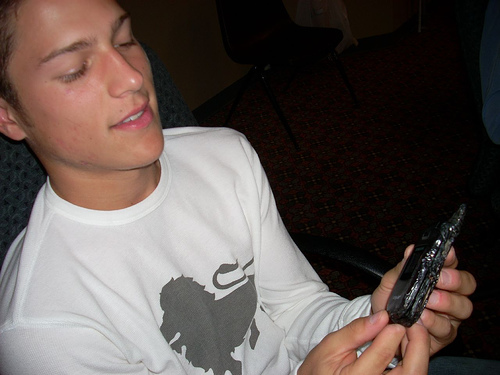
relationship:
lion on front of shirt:
[159, 257, 266, 374] [0, 125, 398, 373]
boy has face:
[1, 2, 266, 373] [35, 10, 163, 153]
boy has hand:
[1, 2, 266, 373] [381, 244, 467, 348]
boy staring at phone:
[1, 2, 266, 373] [387, 207, 464, 325]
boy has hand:
[1, 2, 266, 373] [298, 308, 431, 375]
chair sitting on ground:
[214, 0, 362, 148] [199, 0, 499, 362]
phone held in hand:
[387, 207, 464, 325] [381, 244, 467, 348]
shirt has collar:
[0, 125, 398, 373] [44, 151, 170, 225]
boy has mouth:
[1, 2, 266, 373] [108, 97, 154, 131]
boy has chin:
[1, 2, 266, 373] [130, 127, 165, 168]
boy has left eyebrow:
[1, 2, 266, 373] [110, 10, 133, 41]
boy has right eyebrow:
[1, 2, 266, 373] [35, 35, 93, 68]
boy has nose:
[1, 2, 266, 373] [105, 45, 145, 99]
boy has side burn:
[1, 2, 266, 373] [1, 84, 36, 129]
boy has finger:
[1, 2, 266, 373] [339, 323, 406, 374]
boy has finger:
[1, 2, 266, 373] [435, 266, 477, 296]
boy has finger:
[1, 2, 266, 373] [425, 287, 474, 320]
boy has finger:
[1, 2, 266, 373] [420, 306, 456, 342]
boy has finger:
[1, 2, 266, 373] [388, 317, 432, 375]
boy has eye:
[1, 2, 266, 373] [50, 60, 87, 81]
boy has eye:
[1, 2, 266, 373] [116, 35, 136, 48]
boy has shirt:
[1, 2, 266, 373] [0, 125, 398, 373]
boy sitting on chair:
[1, 2, 266, 373] [1, 62, 396, 312]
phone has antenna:
[387, 207, 464, 325] [439, 199, 470, 244]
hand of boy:
[381, 244, 467, 348] [1, 2, 266, 373]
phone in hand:
[387, 207, 464, 325] [381, 244, 467, 348]